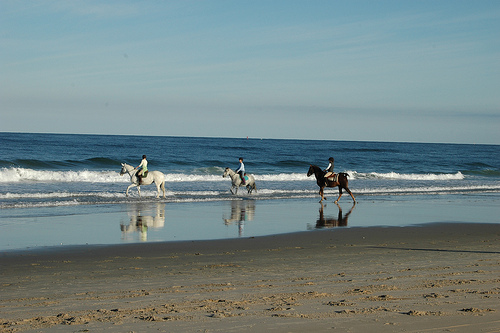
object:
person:
[133, 155, 148, 187]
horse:
[120, 162, 167, 199]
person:
[235, 157, 246, 184]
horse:
[222, 167, 258, 195]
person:
[321, 157, 334, 187]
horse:
[307, 165, 356, 202]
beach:
[0, 223, 500, 333]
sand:
[0, 221, 495, 333]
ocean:
[0, 131, 500, 197]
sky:
[3, 6, 498, 140]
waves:
[4, 166, 469, 189]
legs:
[126, 183, 136, 197]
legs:
[235, 185, 239, 195]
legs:
[318, 186, 323, 203]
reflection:
[120, 201, 165, 241]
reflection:
[223, 197, 257, 235]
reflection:
[307, 200, 355, 230]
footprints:
[207, 310, 218, 316]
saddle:
[135, 170, 148, 177]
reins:
[121, 168, 136, 173]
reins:
[231, 172, 238, 178]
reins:
[312, 169, 325, 173]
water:
[2, 131, 499, 204]